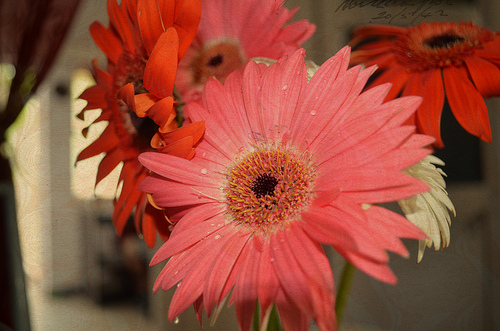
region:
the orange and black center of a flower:
[221, 144, 306, 224]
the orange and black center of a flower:
[119, 76, 185, 133]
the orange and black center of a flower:
[196, 34, 241, 80]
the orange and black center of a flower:
[403, 22, 475, 65]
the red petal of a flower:
[415, 66, 443, 142]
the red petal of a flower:
[370, 60, 405, 102]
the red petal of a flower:
[145, 26, 184, 103]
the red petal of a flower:
[89, 18, 120, 60]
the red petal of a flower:
[72, 125, 119, 161]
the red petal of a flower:
[92, 142, 136, 178]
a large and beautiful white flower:
[405, 149, 462, 239]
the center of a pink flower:
[233, 154, 298, 235]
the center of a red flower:
[106, 85, 157, 145]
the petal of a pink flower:
[250, 224, 323, 314]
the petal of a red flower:
[108, 158, 148, 230]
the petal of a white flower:
[405, 175, 460, 247]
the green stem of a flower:
[317, 246, 377, 330]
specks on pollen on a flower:
[332, 171, 385, 228]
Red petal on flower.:
[454, 83, 484, 132]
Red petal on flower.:
[420, 76, 441, 163]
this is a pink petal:
[274, 213, 343, 283]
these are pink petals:
[143, 184, 355, 329]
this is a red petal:
[133, 20, 188, 110]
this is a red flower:
[324, 13, 496, 132]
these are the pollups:
[183, 33, 258, 85]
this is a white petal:
[393, 176, 443, 283]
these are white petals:
[362, 133, 467, 266]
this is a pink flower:
[117, 69, 429, 313]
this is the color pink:
[171, 185, 179, 194]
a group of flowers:
[66, 6, 488, 327]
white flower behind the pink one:
[138, 30, 460, 329]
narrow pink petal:
[133, 148, 216, 188]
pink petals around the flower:
[115, 47, 440, 327]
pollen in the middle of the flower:
[220, 146, 313, 221]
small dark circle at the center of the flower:
[250, 170, 276, 196]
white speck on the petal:
[211, 230, 222, 240]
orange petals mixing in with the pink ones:
[150, 120, 205, 170]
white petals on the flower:
[366, 145, 461, 260]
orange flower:
[338, 15, 497, 147]